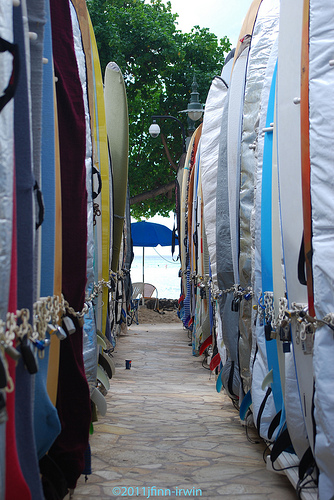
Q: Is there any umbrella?
A: Yes, there is an umbrella.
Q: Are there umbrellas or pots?
A: Yes, there is an umbrella.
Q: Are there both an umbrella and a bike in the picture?
A: No, there is an umbrella but no bikes.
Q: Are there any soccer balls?
A: No, there are no soccer balls.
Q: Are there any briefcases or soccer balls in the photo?
A: No, there are no soccer balls or briefcases.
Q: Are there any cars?
A: No, there are no cars.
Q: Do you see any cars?
A: No, there are no cars.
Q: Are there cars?
A: No, there are no cars.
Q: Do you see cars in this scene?
A: No, there are no cars.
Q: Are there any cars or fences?
A: No, there are no cars or fences.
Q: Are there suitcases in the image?
A: No, there are no suitcases.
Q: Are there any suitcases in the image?
A: No, there are no suitcases.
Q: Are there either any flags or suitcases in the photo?
A: No, there are no suitcases or flags.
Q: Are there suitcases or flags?
A: No, there are no suitcases or flags.